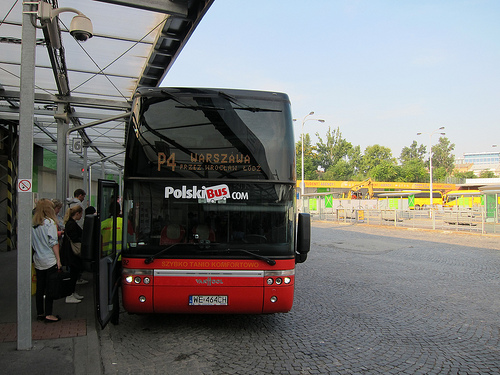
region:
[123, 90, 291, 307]
the bus is red and black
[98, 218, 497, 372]
the street has cobble stones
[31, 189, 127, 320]
the people are standing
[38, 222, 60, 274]
the girl wears a white shirt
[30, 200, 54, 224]
the girl is blonde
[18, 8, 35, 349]
the pole is gray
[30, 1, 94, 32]
the light is white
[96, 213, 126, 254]
the person wears yellow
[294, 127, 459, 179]
the trees are tall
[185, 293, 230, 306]
the bus has a license plate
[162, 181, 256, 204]
company logo with white letters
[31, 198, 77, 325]
woman with long blond hair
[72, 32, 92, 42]
black lens cover over camera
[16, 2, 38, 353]
silver utility pole in concrete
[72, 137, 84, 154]
plattform number sign with the letter 6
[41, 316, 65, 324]
woman wearing black shoes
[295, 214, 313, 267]
black mirror on side of bus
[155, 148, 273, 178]
yellow route letters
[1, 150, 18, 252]
column with black and yellow stripes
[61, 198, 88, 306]
woman wearing black top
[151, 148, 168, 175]
letter p on bus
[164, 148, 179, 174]
number four on bus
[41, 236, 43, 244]
woman wearing white shirt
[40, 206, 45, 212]
woman with blonde hair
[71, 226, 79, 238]
woman wearing black coat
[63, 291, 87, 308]
woman with white shoes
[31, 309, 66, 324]
woman with black shoes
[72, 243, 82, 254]
woman with tan bag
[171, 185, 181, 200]
letter o on bus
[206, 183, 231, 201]
word bus in red lettering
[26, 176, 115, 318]
people at the bus station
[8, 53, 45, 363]
the pole is gray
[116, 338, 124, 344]
part of an elbow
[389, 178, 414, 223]
part of a chair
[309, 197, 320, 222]
part of a window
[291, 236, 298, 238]
edge of a mirror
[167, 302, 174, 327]
part of a light